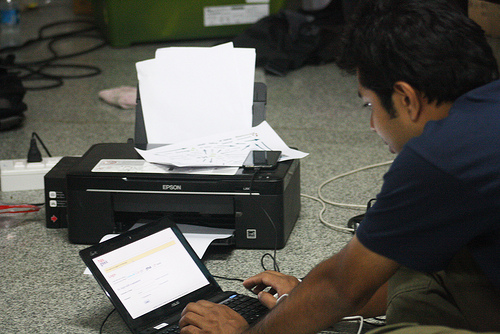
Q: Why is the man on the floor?
A: Printing.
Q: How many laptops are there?
A: 1.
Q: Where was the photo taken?
A: Room.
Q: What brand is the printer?
A: Epson.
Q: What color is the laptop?
A: Black.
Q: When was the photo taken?
A: Night.